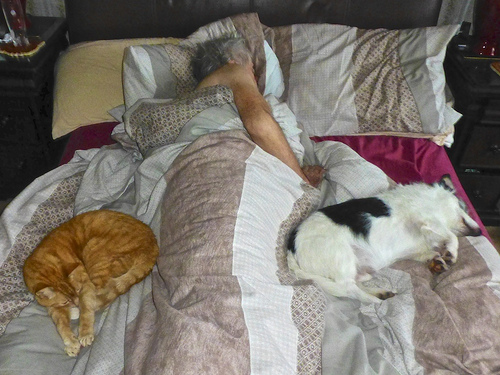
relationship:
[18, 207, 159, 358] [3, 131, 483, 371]
cat sleeping on top of cover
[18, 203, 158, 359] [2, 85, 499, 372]
cat sleeping on top of cover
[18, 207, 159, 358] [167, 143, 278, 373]
cat sleeping on top of cover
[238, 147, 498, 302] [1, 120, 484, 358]
cat sleeping on top of cover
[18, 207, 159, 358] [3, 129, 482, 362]
cat sleeping on top of bed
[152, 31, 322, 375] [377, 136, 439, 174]
man sleeping in bed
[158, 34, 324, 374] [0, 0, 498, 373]
man sleeping bed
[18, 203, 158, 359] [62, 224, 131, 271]
cat with stripes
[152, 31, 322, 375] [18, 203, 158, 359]
man sleeping with cat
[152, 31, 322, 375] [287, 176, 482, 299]
man sleeping with dog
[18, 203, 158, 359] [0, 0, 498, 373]
cat on bed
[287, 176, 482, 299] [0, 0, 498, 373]
dog on bed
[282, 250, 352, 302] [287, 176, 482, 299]
tail on dog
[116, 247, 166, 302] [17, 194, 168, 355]
tail on cat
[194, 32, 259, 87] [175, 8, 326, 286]
head on person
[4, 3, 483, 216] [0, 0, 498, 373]
tables next to bed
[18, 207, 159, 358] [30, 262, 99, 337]
cat has head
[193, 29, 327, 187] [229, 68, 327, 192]
arm of person